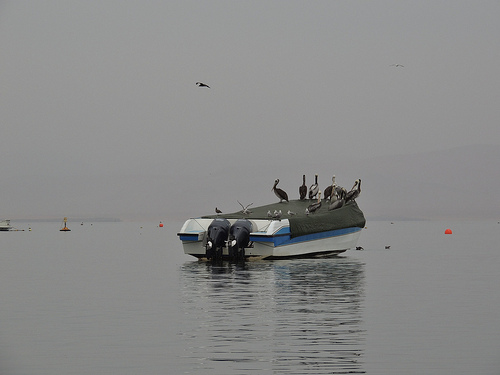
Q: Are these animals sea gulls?
A: No, there are both sea gulls and birds.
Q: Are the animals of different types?
A: Yes, they are sea gulls and birds.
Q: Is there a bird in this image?
A: Yes, there is a bird.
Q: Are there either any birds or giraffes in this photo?
A: Yes, there is a bird.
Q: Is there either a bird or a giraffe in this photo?
A: Yes, there is a bird.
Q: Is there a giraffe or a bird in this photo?
A: Yes, there is a bird.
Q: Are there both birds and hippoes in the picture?
A: No, there is a bird but no hippoes.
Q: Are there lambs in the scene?
A: No, there are no lambs.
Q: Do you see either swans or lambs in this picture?
A: No, there are no lambs or swans.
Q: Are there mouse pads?
A: No, there are no mouse pads.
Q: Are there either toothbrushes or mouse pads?
A: No, there are no mouse pads or toothbrushes.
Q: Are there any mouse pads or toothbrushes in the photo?
A: No, there are no mouse pads or toothbrushes.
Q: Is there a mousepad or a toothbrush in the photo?
A: No, there are no mouse pads or toothbrushes.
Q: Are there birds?
A: Yes, there are birds.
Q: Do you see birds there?
A: Yes, there are birds.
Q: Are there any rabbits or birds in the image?
A: Yes, there are birds.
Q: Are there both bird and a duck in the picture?
A: No, there are birds but no ducks.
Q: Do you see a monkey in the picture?
A: No, there are no monkeys.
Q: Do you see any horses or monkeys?
A: No, there are no monkeys or horses.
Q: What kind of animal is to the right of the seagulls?
A: The animals are birds.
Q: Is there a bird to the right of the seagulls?
A: Yes, there are birds to the right of the seagulls.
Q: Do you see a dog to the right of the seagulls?
A: No, there are birds to the right of the seagulls.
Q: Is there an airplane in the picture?
A: No, there are no airplanes.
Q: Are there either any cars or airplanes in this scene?
A: No, there are no airplanes or cars.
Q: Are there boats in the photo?
A: Yes, there is a boat.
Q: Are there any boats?
A: Yes, there is a boat.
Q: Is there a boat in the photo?
A: Yes, there is a boat.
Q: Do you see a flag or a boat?
A: Yes, there is a boat.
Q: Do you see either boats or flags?
A: Yes, there is a boat.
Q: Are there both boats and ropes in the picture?
A: No, there is a boat but no ropes.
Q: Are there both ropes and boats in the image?
A: No, there is a boat but no ropes.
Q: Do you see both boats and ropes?
A: No, there is a boat but no ropes.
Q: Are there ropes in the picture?
A: No, there are no ropes.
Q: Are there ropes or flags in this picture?
A: No, there are no ropes or flags.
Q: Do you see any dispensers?
A: No, there are no dispensers.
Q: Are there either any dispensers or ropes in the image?
A: No, there are no dispensers or ropes.